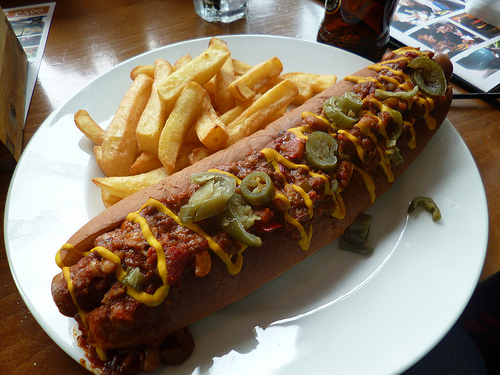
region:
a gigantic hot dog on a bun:
[54, 46, 456, 350]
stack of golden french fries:
[75, 40, 337, 205]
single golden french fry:
[95, 71, 151, 171]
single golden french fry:
[155, 48, 230, 102]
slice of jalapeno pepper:
[242, 173, 272, 201]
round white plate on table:
[1, 27, 493, 372]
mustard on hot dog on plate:
[116, 190, 253, 305]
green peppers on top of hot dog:
[162, 54, 449, 256]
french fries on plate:
[63, 31, 339, 212]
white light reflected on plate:
[190, 318, 309, 373]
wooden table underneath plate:
[3, 2, 499, 374]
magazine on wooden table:
[386, 2, 498, 101]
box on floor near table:
[2, 0, 54, 163]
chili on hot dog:
[56, 43, 438, 373]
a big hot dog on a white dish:
[0, 29, 493, 371]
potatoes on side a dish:
[62, 25, 347, 209]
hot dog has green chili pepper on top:
[2, 23, 494, 373]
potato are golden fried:
[65, 26, 345, 211]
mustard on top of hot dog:
[39, 31, 462, 359]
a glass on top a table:
[188, 0, 255, 28]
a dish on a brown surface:
[10, 5, 498, 374]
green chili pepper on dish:
[399, 188, 453, 228]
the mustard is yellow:
[93, 203, 178, 313]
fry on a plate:
[72, 97, 104, 147]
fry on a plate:
[106, 100, 126, 170]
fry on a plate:
[80, 171, 135, 192]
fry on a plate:
[141, 103, 159, 154]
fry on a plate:
[170, 78, 206, 114]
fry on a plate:
[182, 45, 237, 75]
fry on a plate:
[295, 62, 337, 87]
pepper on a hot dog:
[185, 175, 230, 211]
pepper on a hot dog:
[312, 121, 338, 171]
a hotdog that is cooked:
[55, 148, 347, 310]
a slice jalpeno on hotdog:
[169, 168, 226, 237]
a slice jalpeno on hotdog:
[314, 120, 342, 172]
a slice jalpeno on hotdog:
[341, 83, 376, 137]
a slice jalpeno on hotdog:
[403, 61, 444, 132]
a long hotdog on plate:
[61, 143, 325, 350]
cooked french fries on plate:
[77, 33, 264, 180]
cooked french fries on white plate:
[92, 55, 290, 195]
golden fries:
[121, 75, 251, 138]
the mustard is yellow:
[202, 239, 232, 259]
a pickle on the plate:
[409, 191, 444, 223]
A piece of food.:
[240, 163, 275, 202]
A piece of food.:
[184, 164, 231, 223]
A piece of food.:
[221, 210, 257, 247]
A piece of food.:
[304, 124, 339, 172]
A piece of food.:
[319, 88, 386, 138]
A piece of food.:
[414, 57, 444, 99]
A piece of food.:
[143, 74, 202, 153]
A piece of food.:
[88, 59, 147, 171]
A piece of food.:
[221, 55, 278, 92]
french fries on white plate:
[70, 33, 343, 219]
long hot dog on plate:
[43, 42, 454, 358]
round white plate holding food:
[1, 30, 493, 372]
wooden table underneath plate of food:
[2, 0, 497, 374]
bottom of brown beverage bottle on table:
[313, 0, 403, 62]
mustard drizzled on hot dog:
[51, 43, 431, 367]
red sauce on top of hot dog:
[93, 211, 202, 333]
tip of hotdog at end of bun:
[44, 265, 83, 322]